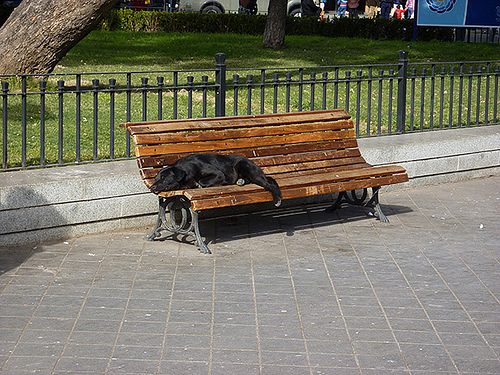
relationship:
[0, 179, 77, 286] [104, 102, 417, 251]
shadow near bench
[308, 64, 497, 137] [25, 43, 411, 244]
fence behind bench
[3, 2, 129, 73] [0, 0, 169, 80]
tree trunk of a tree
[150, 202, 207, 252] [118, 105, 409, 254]
leg on bench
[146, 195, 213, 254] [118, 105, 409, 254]
leg of bench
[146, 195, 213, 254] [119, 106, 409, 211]
leg on a bench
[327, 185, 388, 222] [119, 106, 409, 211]
leg on a bench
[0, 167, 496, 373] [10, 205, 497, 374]
tile on ground